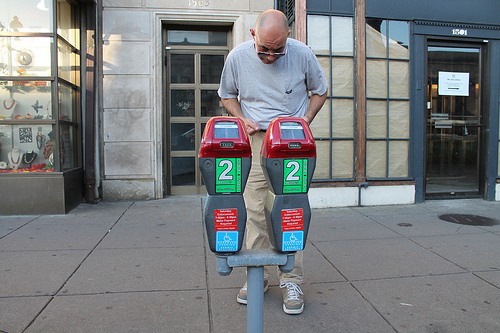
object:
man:
[216, 8, 329, 313]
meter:
[197, 115, 254, 254]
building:
[82, 0, 499, 209]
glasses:
[257, 43, 285, 69]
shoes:
[281, 276, 305, 313]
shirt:
[216, 38, 329, 131]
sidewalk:
[3, 214, 205, 324]